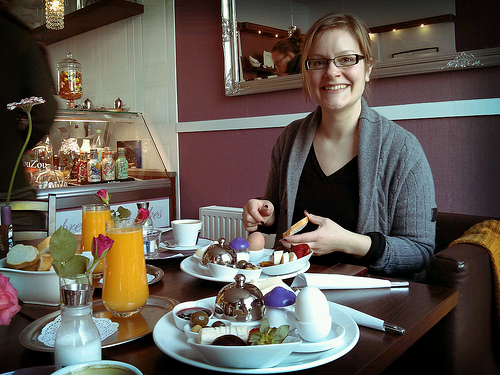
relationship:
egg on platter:
[295, 284, 331, 323] [152, 296, 362, 369]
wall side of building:
[175, 5, 499, 270] [6, 3, 489, 374]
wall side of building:
[175, 5, 499, 270] [86, 15, 211, 150]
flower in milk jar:
[85, 233, 113, 284] [55, 281, 101, 370]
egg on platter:
[295, 284, 331, 343] [150, 290, 362, 373]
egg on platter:
[245, 230, 266, 250] [178, 248, 308, 281]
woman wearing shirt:
[240, 10, 436, 271] [295, 146, 362, 233]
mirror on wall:
[387, 7, 459, 44] [44, 0, 498, 233]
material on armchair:
[483, 225, 498, 244] [458, 248, 487, 342]